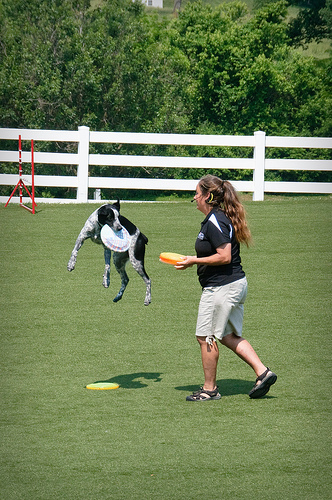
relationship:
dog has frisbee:
[66, 196, 152, 307] [97, 221, 133, 258]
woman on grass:
[173, 173, 279, 403] [3, 202, 319, 488]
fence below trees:
[0, 123, 331, 211] [0, 1, 331, 130]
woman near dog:
[173, 173, 279, 403] [66, 196, 152, 307]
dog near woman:
[66, 196, 152, 307] [173, 173, 279, 403]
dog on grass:
[66, 196, 152, 307] [3, 202, 319, 488]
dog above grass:
[66, 196, 152, 307] [3, 202, 319, 488]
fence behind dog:
[0, 123, 331, 211] [66, 196, 152, 307]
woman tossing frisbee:
[173, 173, 279, 403] [157, 249, 190, 265]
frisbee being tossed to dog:
[157, 249, 190, 265] [66, 196, 152, 307]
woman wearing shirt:
[173, 173, 279, 403] [193, 205, 245, 290]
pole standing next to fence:
[29, 138, 35, 212] [2, 121, 320, 203]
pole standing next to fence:
[17, 134, 23, 205] [2, 121, 320, 203]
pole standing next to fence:
[20, 203, 35, 213] [2, 121, 320, 203]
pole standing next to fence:
[3, 180, 19, 207] [2, 121, 320, 203]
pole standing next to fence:
[20, 179, 37, 206] [2, 121, 320, 203]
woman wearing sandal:
[173, 173, 279, 403] [185, 385, 221, 402]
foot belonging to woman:
[187, 385, 220, 400] [173, 173, 279, 403]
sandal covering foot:
[185, 385, 221, 402] [187, 385, 220, 400]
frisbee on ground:
[87, 381, 124, 399] [2, 202, 317, 491]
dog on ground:
[66, 196, 152, 307] [2, 202, 317, 491]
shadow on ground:
[98, 364, 161, 401] [2, 202, 317, 491]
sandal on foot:
[248, 367, 277, 400] [187, 385, 220, 400]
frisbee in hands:
[159, 251, 194, 268] [174, 253, 195, 274]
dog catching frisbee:
[66, 196, 152, 307] [94, 217, 139, 258]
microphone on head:
[187, 196, 214, 204] [189, 172, 230, 216]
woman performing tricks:
[173, 173, 279, 403] [67, 172, 275, 420]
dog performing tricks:
[69, 196, 154, 301] [67, 172, 275, 420]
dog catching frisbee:
[66, 196, 152, 307] [98, 225, 134, 255]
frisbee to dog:
[159, 251, 194, 268] [66, 196, 152, 307]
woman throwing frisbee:
[173, 173, 279, 403] [159, 251, 194, 268]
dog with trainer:
[66, 196, 152, 307] [156, 177, 275, 409]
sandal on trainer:
[185, 385, 223, 402] [177, 169, 282, 397]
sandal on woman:
[190, 367, 276, 403] [173, 173, 279, 403]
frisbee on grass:
[85, 381, 120, 391] [3, 202, 319, 488]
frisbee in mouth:
[96, 220, 135, 258] [105, 218, 125, 232]